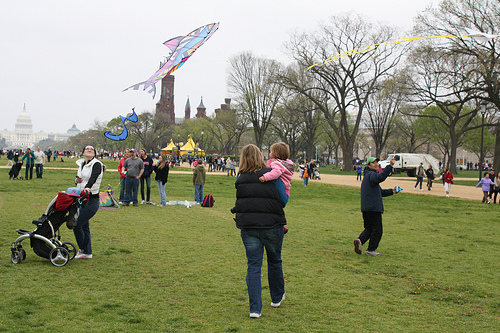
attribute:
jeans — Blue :
[239, 220, 286, 315]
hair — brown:
[268, 138, 289, 160]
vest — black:
[228, 168, 290, 233]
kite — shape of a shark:
[123, 20, 223, 97]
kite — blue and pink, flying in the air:
[104, 19, 221, 139]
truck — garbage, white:
[377, 150, 441, 171]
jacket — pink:
[267, 150, 299, 189]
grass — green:
[0, 163, 497, 330]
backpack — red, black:
[199, 191, 217, 209]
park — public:
[2, 150, 494, 327]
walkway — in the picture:
[451, 182, 480, 198]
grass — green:
[9, 272, 496, 331]